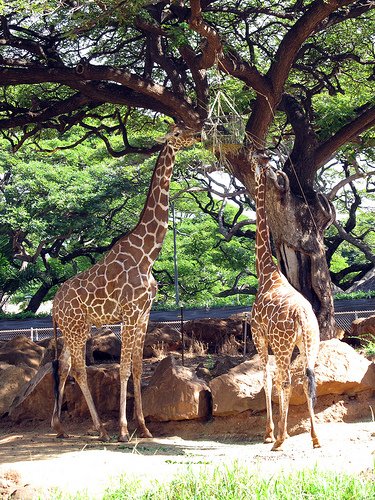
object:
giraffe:
[250, 151, 322, 452]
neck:
[105, 148, 179, 266]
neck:
[255, 186, 293, 287]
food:
[199, 90, 246, 174]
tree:
[0, 0, 375, 322]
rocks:
[0, 312, 374, 420]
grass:
[37, 461, 374, 499]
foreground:
[0, 421, 373, 500]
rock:
[209, 337, 375, 417]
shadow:
[154, 418, 264, 445]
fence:
[0, 307, 374, 352]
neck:
[255, 173, 282, 274]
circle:
[0, 311, 375, 458]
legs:
[51, 316, 150, 442]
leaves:
[0, 103, 169, 260]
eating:
[152, 89, 277, 175]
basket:
[204, 90, 241, 159]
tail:
[306, 368, 318, 408]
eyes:
[174, 132, 179, 137]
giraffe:
[51, 119, 197, 442]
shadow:
[0, 431, 186, 462]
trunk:
[234, 171, 335, 342]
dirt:
[0, 417, 375, 485]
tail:
[51, 318, 60, 425]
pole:
[171, 197, 178, 307]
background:
[0, 146, 374, 321]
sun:
[130, 339, 374, 461]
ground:
[0, 311, 373, 498]